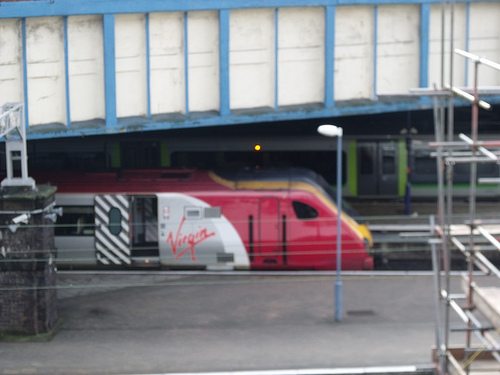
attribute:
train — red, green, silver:
[149, 162, 381, 260]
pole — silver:
[311, 120, 369, 325]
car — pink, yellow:
[170, 189, 375, 268]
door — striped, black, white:
[93, 187, 132, 273]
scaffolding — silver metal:
[413, 44, 499, 371]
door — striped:
[95, 202, 131, 269]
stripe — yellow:
[204, 166, 373, 251]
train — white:
[2, 169, 373, 269]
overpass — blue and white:
[1, 2, 498, 148]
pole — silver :
[317, 126, 362, 336]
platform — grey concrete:
[1, 272, 498, 373]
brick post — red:
[0, 186, 55, 342]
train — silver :
[34, 166, 379, 270]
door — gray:
[378, 142, 400, 195]